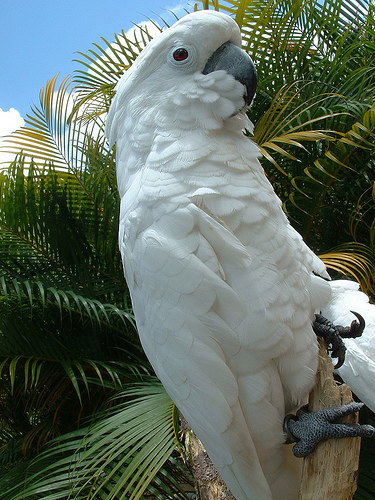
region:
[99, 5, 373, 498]
a parrot on a stick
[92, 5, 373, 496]
a parrot white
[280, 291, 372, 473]
fingers of a parrot are black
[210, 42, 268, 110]
peak of parrot is black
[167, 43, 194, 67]
black eye of parrot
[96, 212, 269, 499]
wings of parrot is white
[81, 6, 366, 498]
parrot in middle of trees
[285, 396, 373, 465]
tree fingers on right leg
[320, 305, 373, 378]
two claws can be seen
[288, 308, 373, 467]
finger used to hold in a log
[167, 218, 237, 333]
A parrot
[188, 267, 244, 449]
A parrot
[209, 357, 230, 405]
A parrot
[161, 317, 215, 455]
A parrot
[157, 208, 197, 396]
A parrot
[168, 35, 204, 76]
a parrots right eye.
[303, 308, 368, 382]
the claws of a parrot.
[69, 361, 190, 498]
a green palm leaf.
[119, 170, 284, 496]
the right wing of a bird.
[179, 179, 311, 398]
the front of a bird.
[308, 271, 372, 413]
a right wing of a bird.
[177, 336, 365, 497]
a bird on a wooden post.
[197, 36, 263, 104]
a parrot's black beak.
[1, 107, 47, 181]
a white cloud behind a palm tree.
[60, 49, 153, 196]
the top of a parrot's head.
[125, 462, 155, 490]
the leaf is green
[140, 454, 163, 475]
the leaf is green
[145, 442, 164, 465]
the leaf is green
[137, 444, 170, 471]
the leaf is green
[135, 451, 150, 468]
the leaf is green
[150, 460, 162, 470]
the leaf is green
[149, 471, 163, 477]
the leaf is green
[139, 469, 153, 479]
the leaf is green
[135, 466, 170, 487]
the leaf is green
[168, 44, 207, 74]
a bird's right eye.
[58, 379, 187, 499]
a green palm tree leaf.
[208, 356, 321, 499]
the tail feathers of a bird.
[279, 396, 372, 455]
a black foot of a bird.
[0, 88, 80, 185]
a cloud in a blue sky.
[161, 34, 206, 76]
the right eye of a bird.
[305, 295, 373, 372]
the black claw of a bird.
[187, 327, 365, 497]
a piece of wood.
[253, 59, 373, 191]
palm tree leaves.